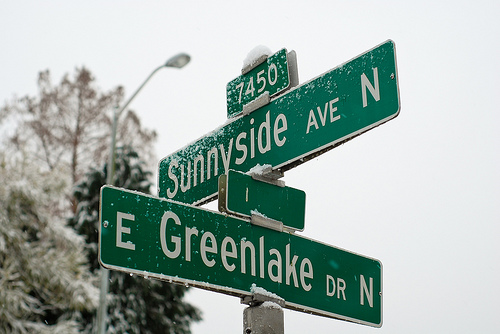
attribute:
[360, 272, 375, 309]
letter — white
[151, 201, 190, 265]
letter — white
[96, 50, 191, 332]
street light — silver, metal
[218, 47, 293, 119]
street sign — green , metal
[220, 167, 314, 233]
empty sign — small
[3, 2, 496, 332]
sky — gray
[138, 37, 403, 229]
street sign — silver, metal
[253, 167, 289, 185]
brackets — sign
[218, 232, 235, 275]
letter — white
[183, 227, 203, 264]
letter — white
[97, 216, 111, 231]
bolt — silver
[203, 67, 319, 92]
sign — small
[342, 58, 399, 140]
letter — white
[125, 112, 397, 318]
street signs — stacked, metal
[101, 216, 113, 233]
bolt — silver , metal 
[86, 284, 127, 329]
pole — silver and metal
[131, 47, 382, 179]
sign — blank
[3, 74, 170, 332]
tree — brown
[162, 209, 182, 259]
letter — white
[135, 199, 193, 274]
letter — white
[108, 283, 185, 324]
leaves — green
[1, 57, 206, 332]
tree — tall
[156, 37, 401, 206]
sign — silver ane metal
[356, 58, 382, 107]
letter — white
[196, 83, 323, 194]
letter — white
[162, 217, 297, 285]
letter — white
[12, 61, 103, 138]
leaves — dead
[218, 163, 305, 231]
sign — faded, street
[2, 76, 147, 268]
leaves — brown